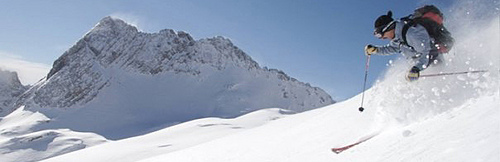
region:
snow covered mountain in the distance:
[49, 14, 289, 119]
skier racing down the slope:
[341, 6, 485, 136]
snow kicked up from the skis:
[405, 77, 462, 120]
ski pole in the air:
[327, 40, 382, 131]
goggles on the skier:
[369, 15, 397, 37]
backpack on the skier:
[404, 3, 464, 50]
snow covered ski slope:
[159, 131, 284, 156]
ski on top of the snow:
[322, 134, 368, 157]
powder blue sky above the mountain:
[265, 16, 339, 56]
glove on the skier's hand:
[364, 40, 379, 56]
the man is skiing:
[333, 6, 452, 134]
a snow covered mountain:
[38, 31, 213, 144]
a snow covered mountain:
[63, 14, 287, 134]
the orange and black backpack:
[412, 5, 456, 55]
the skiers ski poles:
[354, 38, 481, 110]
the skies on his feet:
[319, 98, 488, 160]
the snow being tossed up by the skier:
[375, 57, 483, 128]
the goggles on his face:
[364, 16, 408, 41]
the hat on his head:
[372, 11, 415, 38]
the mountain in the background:
[34, 13, 330, 105]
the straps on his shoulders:
[394, 13, 421, 48]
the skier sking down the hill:
[362, 13, 452, 140]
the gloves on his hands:
[354, 41, 429, 87]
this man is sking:
[63, 13, 479, 156]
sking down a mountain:
[63, 10, 491, 112]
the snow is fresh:
[41, 10, 496, 158]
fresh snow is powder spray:
[51, 10, 469, 137]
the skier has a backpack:
[324, 12, 486, 137]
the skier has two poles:
[310, 0, 493, 119]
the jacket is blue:
[331, 19, 461, 151]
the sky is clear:
[34, 16, 413, 145]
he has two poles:
[346, 9, 484, 156]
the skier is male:
[320, 14, 482, 131]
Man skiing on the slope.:
[330, 1, 490, 158]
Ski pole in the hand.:
[354, 33, 378, 113]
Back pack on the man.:
[368, 3, 451, 54]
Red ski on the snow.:
[332, 123, 364, 157]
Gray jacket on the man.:
[363, 11, 435, 80]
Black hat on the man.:
[367, 11, 393, 42]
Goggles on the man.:
[371, 18, 397, 41]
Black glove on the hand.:
[400, 59, 422, 84]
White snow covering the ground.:
[3, 73, 498, 160]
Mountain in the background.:
[23, 9, 334, 128]